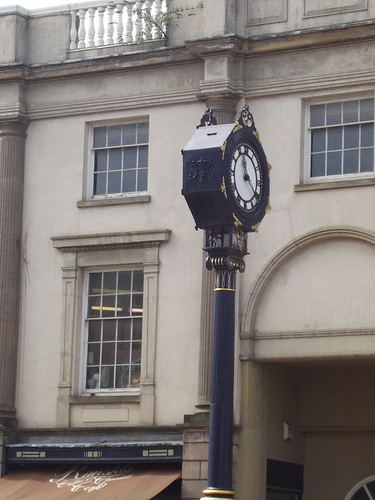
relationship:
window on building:
[303, 102, 358, 159] [2, 0, 374, 498]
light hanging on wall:
[88, 295, 129, 316] [90, 273, 143, 339]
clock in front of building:
[145, 56, 355, 382] [19, 23, 371, 370]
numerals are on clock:
[236, 191, 251, 210] [228, 144, 267, 216]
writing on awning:
[44, 463, 145, 497] [1, 466, 182, 497]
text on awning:
[44, 466, 143, 493] [16, 429, 211, 498]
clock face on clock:
[228, 142, 264, 212] [172, 102, 309, 247]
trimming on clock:
[196, 484, 238, 498] [230, 140, 269, 216]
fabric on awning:
[5, 475, 148, 498] [8, 465, 180, 498]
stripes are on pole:
[198, 485, 235, 497] [199, 276, 241, 498]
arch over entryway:
[238, 234, 373, 339] [249, 360, 371, 496]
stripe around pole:
[211, 286, 236, 291] [201, 270, 235, 499]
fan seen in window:
[84, 364, 112, 396] [77, 268, 144, 400]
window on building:
[77, 268, 144, 400] [2, 0, 374, 498]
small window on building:
[92, 122, 148, 194] [2, 0, 374, 498]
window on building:
[308, 98, 373, 176] [2, 0, 374, 498]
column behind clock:
[197, 249, 213, 441] [230, 129, 265, 219]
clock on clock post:
[181, 121, 269, 232] [201, 255, 241, 500]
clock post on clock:
[201, 255, 241, 500] [196, 125, 310, 206]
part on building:
[0, 23, 373, 119] [2, 0, 374, 498]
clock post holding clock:
[201, 255, 241, 500] [180, 114, 273, 234]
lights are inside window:
[91, 303, 143, 317] [85, 270, 143, 386]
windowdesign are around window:
[50, 228, 170, 427] [82, 269, 140, 393]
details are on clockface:
[218, 174, 229, 199] [228, 140, 265, 215]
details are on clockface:
[217, 138, 228, 161] [228, 140, 265, 215]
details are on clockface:
[229, 118, 244, 132] [228, 140, 265, 215]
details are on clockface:
[249, 127, 263, 146] [228, 140, 265, 215]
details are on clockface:
[263, 156, 273, 176] [228, 140, 265, 215]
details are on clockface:
[261, 195, 272, 214] [228, 140, 265, 215]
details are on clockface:
[249, 218, 263, 234] [228, 140, 265, 215]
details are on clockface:
[229, 209, 245, 228] [228, 140, 265, 215]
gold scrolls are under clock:
[207, 257, 245, 273] [223, 144, 261, 211]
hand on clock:
[240, 151, 249, 179] [180, 102, 272, 232]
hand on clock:
[243, 173, 259, 199] [180, 102, 272, 232]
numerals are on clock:
[225, 145, 263, 213] [180, 122, 270, 231]